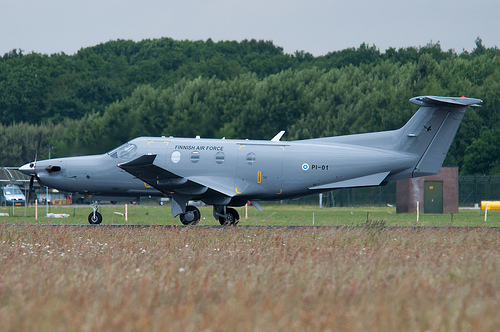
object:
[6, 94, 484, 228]
airplane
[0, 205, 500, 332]
field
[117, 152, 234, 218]
wing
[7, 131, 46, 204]
propeller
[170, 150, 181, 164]
windows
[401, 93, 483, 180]
tail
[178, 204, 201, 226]
wheel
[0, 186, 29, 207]
van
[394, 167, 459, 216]
building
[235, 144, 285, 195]
door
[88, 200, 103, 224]
landing gear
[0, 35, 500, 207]
forest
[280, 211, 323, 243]
air strip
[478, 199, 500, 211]
barrel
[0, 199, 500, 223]
fence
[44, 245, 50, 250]
flowers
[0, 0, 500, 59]
sky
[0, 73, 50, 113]
tree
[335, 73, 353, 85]
leaves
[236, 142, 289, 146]
stripe